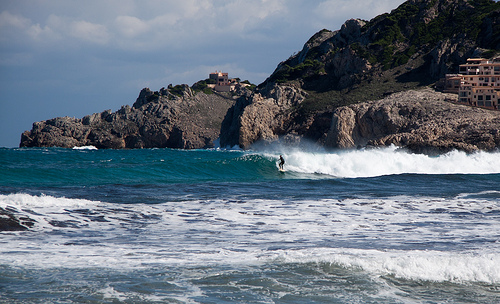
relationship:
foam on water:
[2, 189, 497, 302] [33, 145, 495, 302]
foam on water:
[214, 135, 499, 180] [33, 145, 495, 302]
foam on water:
[71, 140, 99, 150] [33, 145, 495, 302]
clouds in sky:
[0, 0, 401, 70] [1, 0, 404, 150]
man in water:
[277, 155, 284, 171] [33, 145, 495, 302]